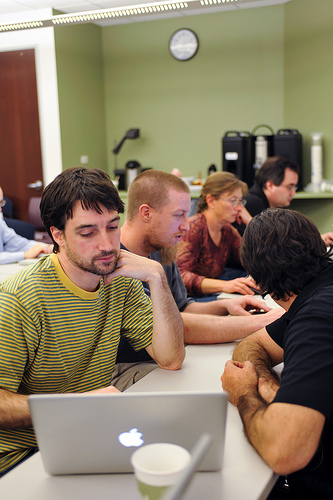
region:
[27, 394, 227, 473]
a silver apple computer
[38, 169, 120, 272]
man with dark hair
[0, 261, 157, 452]
blue and yellow striped shirt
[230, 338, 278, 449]
thick black hair on arms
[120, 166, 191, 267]
man with a long beard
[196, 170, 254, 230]
woman leaning on her hand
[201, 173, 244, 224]
woman wearing glasses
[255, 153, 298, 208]
man with black hair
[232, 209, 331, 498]
man wearing a black shirt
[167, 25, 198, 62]
black and white clock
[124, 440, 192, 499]
the cup on the table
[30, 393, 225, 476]
the back of the mac laptop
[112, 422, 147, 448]
the white apple logo lite up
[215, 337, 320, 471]
the mans arms on the table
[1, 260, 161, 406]
a yellow shirt with blue stripes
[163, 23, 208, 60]
the round wall clock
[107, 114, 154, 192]
the projector in the classroom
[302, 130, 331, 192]
a stack of cups on the table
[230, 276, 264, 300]
the hand on the black mouse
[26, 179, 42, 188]
the handle for the door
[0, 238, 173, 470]
this is a shirt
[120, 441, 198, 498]
this is a cup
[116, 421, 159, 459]
this is the apple logo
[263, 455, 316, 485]
this is an elbow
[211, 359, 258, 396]
this is a hand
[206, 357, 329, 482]
this is an arm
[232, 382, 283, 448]
this is a forearm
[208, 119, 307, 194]
this is a coffee maker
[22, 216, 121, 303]
this is a shirt collar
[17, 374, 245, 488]
this is a laptop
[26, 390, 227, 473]
silver computer with the apple label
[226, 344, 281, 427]
thick hair on arms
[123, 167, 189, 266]
man with a buzzed head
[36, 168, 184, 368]
man leaning on his hand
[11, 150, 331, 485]
a group of people at a long desk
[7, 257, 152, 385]
yellow and blue striped shirt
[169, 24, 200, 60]
large clock hangs on wall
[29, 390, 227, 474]
al apple laptop computer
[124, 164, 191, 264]
man with red goatee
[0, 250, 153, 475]
striped wello and black t-shirt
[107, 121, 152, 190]
overhead projector at back of room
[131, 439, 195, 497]
green and white styrofoam cup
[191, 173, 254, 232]
a head rests on a hand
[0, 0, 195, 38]
overhead fluorescent lighting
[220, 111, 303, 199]
commercial thermal coffee dispensers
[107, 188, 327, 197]
a green counter along back wall